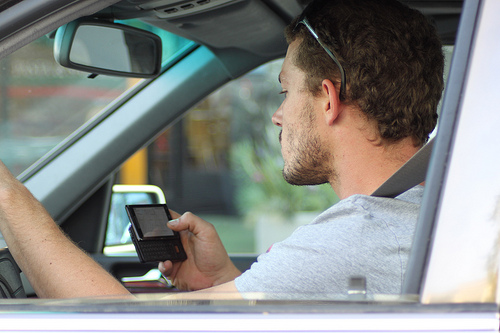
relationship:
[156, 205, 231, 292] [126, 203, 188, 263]
hand holding cell phone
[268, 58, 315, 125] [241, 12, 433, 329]
eye of person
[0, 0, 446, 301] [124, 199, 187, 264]
man holding phone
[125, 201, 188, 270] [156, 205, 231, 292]
phone in hand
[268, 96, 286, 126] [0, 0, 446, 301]
nose on man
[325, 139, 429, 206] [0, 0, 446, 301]
neck of man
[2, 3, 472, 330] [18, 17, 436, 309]
driver side has window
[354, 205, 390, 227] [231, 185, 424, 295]
spot on shirt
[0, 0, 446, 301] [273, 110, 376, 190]
man has beard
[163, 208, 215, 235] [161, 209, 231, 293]
thumb on hand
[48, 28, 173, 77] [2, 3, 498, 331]
mirror on car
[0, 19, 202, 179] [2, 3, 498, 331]
windshield on car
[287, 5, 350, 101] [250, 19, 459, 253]
sunglasses glasses on top of a head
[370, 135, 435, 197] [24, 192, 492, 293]
seat belt belt in a car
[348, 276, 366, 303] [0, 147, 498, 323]
window lock at side of car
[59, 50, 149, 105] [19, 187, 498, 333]
front mirror in car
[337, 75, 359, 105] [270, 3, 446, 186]
edge of glasses on head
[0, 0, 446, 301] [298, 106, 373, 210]
man with sunglasses on h head